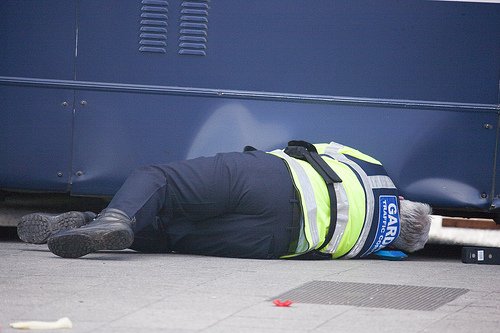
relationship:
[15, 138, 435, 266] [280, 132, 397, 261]
man in vest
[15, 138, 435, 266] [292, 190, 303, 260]
man in belt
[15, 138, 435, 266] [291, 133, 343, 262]
man in belt